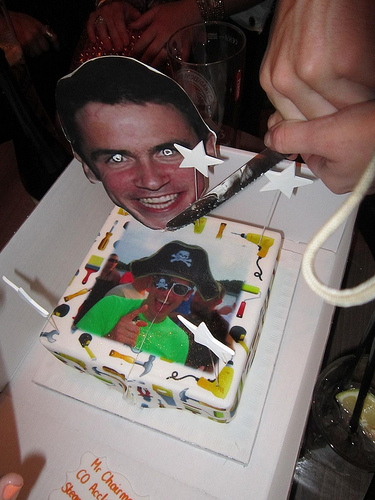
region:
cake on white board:
[92, 217, 278, 496]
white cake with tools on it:
[82, 217, 264, 444]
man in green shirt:
[123, 216, 205, 388]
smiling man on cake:
[107, 229, 235, 415]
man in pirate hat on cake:
[122, 237, 228, 385]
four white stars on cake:
[0, 140, 314, 398]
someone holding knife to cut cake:
[158, 118, 320, 260]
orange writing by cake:
[51, 439, 129, 497]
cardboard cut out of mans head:
[29, 66, 247, 244]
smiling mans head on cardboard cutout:
[48, 65, 239, 251]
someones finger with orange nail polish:
[0, 471, 25, 499]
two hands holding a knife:
[166, 1, 374, 230]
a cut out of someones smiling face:
[51, 54, 217, 229]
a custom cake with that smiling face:
[39, 197, 284, 425]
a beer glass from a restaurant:
[165, 19, 247, 145]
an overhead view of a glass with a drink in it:
[311, 351, 374, 472]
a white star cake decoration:
[173, 140, 223, 178]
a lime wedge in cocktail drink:
[335, 387, 374, 441]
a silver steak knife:
[165, 147, 287, 233]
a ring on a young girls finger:
[94, 14, 104, 25]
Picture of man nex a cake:
[46, 48, 223, 233]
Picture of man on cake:
[70, 211, 254, 367]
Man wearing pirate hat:
[72, 234, 234, 365]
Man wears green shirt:
[70, 232, 228, 369]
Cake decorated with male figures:
[23, 179, 297, 429]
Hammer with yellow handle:
[102, 341, 159, 381]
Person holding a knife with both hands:
[145, 2, 374, 237]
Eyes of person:
[98, 143, 178, 170]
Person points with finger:
[75, 229, 226, 373]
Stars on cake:
[163, 134, 317, 204]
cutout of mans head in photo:
[39, 82, 247, 226]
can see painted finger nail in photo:
[3, 452, 52, 495]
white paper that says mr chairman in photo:
[64, 429, 145, 497]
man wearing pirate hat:
[121, 218, 252, 347]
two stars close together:
[171, 136, 324, 230]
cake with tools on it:
[96, 203, 249, 428]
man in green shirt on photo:
[90, 277, 219, 391]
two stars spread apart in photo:
[1, 270, 228, 378]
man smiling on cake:
[126, 252, 200, 383]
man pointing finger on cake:
[72, 242, 224, 393]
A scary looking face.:
[48, 45, 227, 211]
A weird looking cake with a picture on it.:
[27, 196, 296, 411]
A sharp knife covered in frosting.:
[140, 124, 315, 249]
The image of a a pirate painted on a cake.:
[61, 241, 222, 372]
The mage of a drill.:
[163, 352, 246, 406]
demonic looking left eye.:
[153, 141, 183, 173]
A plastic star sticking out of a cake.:
[0, 260, 72, 340]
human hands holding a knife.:
[256, 0, 373, 204]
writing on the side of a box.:
[60, 446, 139, 498]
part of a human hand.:
[7, 390, 61, 498]